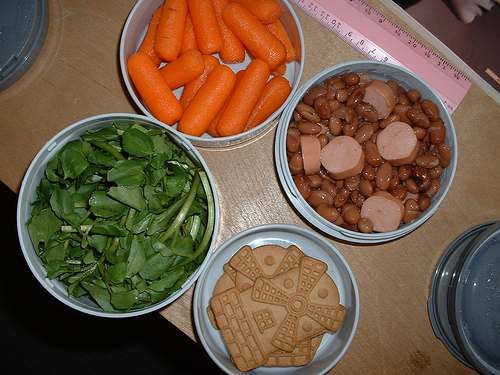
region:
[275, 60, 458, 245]
franks and beans in a blue bowl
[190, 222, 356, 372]
cookies on a blue plate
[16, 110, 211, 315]
greens in a blue container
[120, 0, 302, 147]
carrots in a dish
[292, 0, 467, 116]
a pink ruler on the table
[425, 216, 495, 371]
stack of blue containers to the right of the food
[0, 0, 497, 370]
the wood table the food is on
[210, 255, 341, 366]
a windmill shaped cookie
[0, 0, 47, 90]
a blue container to the left of the food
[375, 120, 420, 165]
a sliced frankfurter in the frank and beans dish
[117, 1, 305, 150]
A bowl of orange baby carrots.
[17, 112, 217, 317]
A bowl of leafy green vegetables.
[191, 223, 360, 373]
A bowl of windmill shaped cookies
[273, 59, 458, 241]
A bowl of beans and franks.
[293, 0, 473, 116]
a pink ruler on the table.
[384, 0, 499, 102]
a fashion magazine behind the ruler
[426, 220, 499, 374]
A stack of blue bowl lids.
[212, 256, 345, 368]
A cookie shaped like a windmill.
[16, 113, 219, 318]
A bowl of lettuce sticking off the table.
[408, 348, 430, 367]
A water spot on the table top.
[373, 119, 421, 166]
piece of a food in a bowl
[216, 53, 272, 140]
piece of a food in a bowl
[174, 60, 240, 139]
piece of a food in a bowl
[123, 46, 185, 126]
piece of a food in a bowl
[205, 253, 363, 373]
piece of a food in a bowl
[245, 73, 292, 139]
piece of a food in a bowl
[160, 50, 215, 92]
piece of a food in a bowl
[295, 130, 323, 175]
piece of a food in a bowl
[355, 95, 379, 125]
piece of a food in a bowl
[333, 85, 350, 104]
piece of a food in a bowl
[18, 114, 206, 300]
Green veggie in white bowl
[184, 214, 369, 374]
Golden brown cookies in a bowl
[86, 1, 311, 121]
Orange veggies in a white bowl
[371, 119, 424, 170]
Brown meat in a bowl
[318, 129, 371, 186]
Brown meat in a bowl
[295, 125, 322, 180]
Brown meat in a bowl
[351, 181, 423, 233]
Brown meat in a bowl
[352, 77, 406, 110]
Brown meat in a bowl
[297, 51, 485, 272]
Brown beans in a bowl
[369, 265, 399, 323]
Light brown wood grain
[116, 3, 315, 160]
peeled small orange carrots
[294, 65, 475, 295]
beans with sausage in a bowl